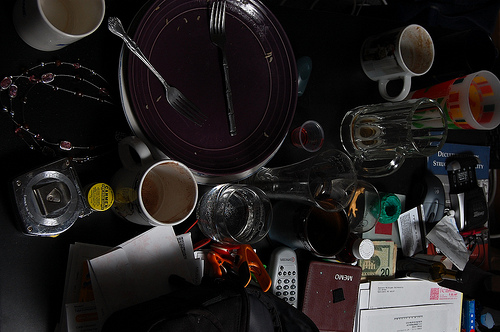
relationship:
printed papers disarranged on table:
[361, 282, 463, 329] [7, 3, 474, 324]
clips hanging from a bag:
[204, 243, 273, 290] [98, 275, 328, 329]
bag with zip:
[224, 257, 315, 326] [237, 259, 257, 291]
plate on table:
[130, 76, 282, 194] [15, 247, 71, 324]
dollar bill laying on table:
[362, 239, 396, 274] [7, 3, 474, 324]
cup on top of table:
[111, 136, 199, 226] [7, 3, 474, 324]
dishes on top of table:
[348, 19, 482, 144] [7, 3, 474, 324]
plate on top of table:
[116, 0, 297, 186] [7, 3, 474, 324]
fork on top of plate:
[205, 1, 241, 136] [116, 0, 297, 186]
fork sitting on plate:
[209, 1, 236, 136] [116, 0, 299, 174]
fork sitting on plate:
[104, 12, 211, 132] [116, 0, 299, 174]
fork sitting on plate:
[108, 17, 209, 127] [116, 0, 299, 174]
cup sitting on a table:
[118, 137, 194, 229] [0, 0, 500, 266]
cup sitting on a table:
[365, 26, 436, 98] [0, 0, 500, 266]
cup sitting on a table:
[25, 3, 107, 50] [0, 0, 500, 266]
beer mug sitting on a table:
[338, 97, 449, 177] [316, 21, 353, 104]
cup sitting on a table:
[361, 24, 435, 102] [316, 21, 353, 104]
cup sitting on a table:
[111, 136, 199, 226] [316, 21, 353, 104]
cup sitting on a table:
[19, 0, 106, 51] [316, 21, 353, 104]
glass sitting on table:
[192, 177, 277, 249] [7, 3, 474, 324]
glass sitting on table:
[254, 148, 356, 215] [7, 3, 474, 324]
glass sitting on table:
[325, 170, 383, 238] [7, 3, 474, 324]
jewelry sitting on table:
[3, 58, 115, 151] [7, 3, 474, 324]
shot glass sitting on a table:
[284, 118, 327, 154] [7, 3, 474, 324]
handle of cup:
[354, 157, 416, 177] [356, 22, 434, 100]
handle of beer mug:
[375, 75, 411, 100] [340, 97, 449, 178]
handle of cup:
[115, 132, 148, 162] [105, 132, 199, 229]